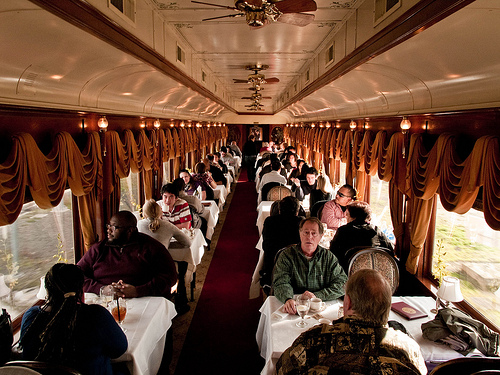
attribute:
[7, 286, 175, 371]
dinning table — for dinning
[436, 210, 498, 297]
windows — multiple, glass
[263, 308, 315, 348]
table — white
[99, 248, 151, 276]
jacket — green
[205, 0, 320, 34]
fan — hanging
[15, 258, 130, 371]
woman — nearest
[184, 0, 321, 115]
fans — ceiling fan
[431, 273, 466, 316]
lamp — small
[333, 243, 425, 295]
chair —  empty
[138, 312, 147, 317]
table — for dinning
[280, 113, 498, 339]
curtains — orange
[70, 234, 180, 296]
sweatshirt — purple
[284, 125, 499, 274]
curtains — brown, hanging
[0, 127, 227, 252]
curtains — hanging, brown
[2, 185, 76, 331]
window — large, glass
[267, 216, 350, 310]
man — sitting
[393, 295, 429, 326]
book — dark colored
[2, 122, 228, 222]
curtains — gold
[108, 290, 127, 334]
glass — for  drink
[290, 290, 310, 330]
glass —  clear